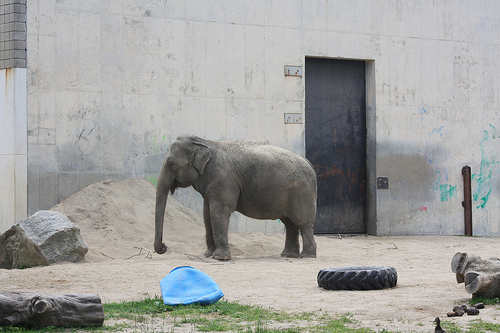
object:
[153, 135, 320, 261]
elephant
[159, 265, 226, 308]
item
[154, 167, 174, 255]
trunk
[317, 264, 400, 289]
tire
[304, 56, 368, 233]
door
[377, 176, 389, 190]
control panel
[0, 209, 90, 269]
stone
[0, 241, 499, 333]
sand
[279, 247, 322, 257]
feet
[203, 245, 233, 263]
feet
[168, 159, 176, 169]
eye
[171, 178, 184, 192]
mouth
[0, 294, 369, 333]
patch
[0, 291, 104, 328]
log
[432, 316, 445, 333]
duckling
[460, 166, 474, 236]
metal post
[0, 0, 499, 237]
wall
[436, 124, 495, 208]
graffiti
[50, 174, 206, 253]
pile of sand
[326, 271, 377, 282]
edge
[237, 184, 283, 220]
stomach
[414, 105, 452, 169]
stuff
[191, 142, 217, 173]
ear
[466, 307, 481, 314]
elephant dung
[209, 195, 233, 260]
part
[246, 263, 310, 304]
dirt